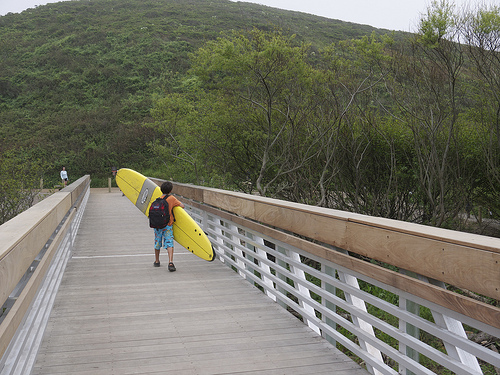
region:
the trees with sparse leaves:
[197, 32, 477, 204]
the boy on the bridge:
[138, 155, 187, 272]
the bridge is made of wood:
[52, 160, 304, 371]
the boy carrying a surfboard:
[133, 166, 187, 273]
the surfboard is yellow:
[108, 155, 222, 270]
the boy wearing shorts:
[128, 168, 186, 268]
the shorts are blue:
[143, 221, 186, 257]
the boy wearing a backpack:
[144, 183, 171, 226]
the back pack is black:
[131, 184, 174, 240]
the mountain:
[38, 5, 468, 188]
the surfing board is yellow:
[82, 161, 165, 251]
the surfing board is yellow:
[99, 173, 278, 310]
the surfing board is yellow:
[89, 98, 261, 345]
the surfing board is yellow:
[80, 52, 257, 368]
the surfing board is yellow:
[103, 153, 240, 363]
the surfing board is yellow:
[131, 191, 226, 362]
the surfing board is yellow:
[131, 145, 232, 336]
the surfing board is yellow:
[109, 121, 236, 368]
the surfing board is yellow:
[116, 138, 223, 351]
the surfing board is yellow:
[119, 145, 258, 360]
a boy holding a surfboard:
[91, 60, 318, 339]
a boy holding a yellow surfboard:
[72, 96, 254, 308]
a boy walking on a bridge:
[57, 50, 254, 356]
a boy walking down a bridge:
[64, 118, 228, 341]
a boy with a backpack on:
[77, 115, 253, 320]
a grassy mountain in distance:
[69, 14, 431, 159]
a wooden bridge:
[14, 155, 431, 370]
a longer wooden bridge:
[23, 135, 361, 372]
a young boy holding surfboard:
[89, 95, 318, 356]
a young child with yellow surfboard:
[47, 91, 301, 373]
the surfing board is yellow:
[74, 146, 293, 315]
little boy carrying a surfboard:
[98, 147, 210, 279]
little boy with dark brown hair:
[105, 114, 249, 296]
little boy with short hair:
[80, 186, 272, 278]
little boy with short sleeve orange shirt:
[88, 156, 234, 305]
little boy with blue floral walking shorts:
[74, 160, 237, 313]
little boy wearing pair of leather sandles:
[101, 162, 218, 327]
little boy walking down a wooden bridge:
[17, 153, 330, 373]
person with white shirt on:
[40, 140, 75, 233]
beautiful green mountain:
[16, 0, 430, 162]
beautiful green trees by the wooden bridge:
[156, 34, 468, 161]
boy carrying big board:
[98, 162, 228, 279]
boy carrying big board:
[105, 156, 228, 278]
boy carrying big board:
[103, 160, 234, 282]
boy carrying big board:
[108, 158, 233, 278]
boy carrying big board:
[108, 158, 223, 282]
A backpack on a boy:
[148, 196, 169, 228]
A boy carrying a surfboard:
[147, 180, 177, 275]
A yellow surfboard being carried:
[114, 162, 216, 262]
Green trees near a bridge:
[142, 0, 498, 240]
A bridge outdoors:
[2, 171, 499, 373]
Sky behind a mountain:
[229, 3, 496, 49]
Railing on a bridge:
[146, 178, 498, 374]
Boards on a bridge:
[24, 183, 371, 370]